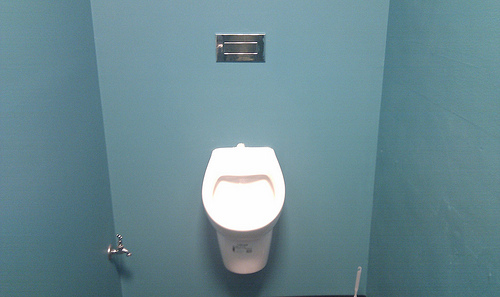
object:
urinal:
[200, 141, 288, 276]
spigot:
[106, 234, 132, 262]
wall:
[306, 20, 378, 110]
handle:
[350, 264, 364, 295]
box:
[215, 33, 266, 64]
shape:
[223, 41, 257, 54]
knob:
[113, 233, 121, 241]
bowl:
[213, 176, 272, 220]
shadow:
[225, 275, 270, 296]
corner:
[374, 42, 391, 80]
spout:
[121, 244, 133, 257]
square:
[220, 39, 260, 61]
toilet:
[200, 141, 288, 274]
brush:
[350, 264, 362, 297]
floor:
[283, 295, 498, 296]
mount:
[223, 33, 262, 57]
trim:
[376, 31, 390, 51]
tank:
[211, 142, 276, 157]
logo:
[227, 242, 257, 256]